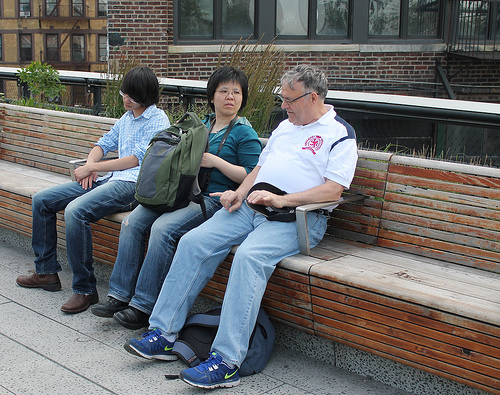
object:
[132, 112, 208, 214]
backpack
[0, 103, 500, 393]
bench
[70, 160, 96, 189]
armrest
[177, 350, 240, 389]
shoes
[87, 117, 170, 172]
arms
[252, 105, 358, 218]
shirt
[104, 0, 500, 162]
wall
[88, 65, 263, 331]
woman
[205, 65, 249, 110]
dark hair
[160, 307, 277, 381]
bag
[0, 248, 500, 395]
sidewalk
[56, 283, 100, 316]
shoes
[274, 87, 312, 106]
glasses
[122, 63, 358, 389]
man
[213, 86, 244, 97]
glasses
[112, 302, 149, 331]
shoes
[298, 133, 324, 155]
emblem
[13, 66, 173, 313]
boy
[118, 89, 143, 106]
glasses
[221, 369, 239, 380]
green check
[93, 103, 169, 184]
shirt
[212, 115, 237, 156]
strap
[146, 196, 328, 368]
jeans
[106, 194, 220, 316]
jeans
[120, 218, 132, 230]
tear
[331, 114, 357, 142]
blue trim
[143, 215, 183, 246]
lap